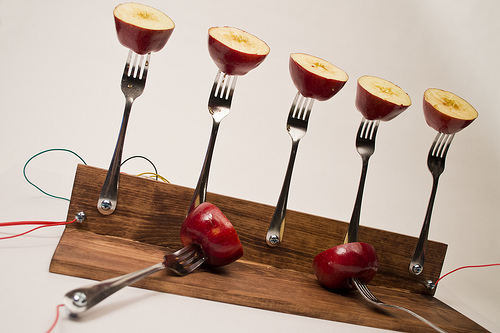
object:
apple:
[313, 241, 379, 293]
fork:
[350, 275, 447, 332]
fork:
[97, 50, 152, 216]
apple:
[113, 2, 177, 55]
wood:
[47, 163, 489, 332]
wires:
[23, 148, 88, 201]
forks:
[409, 131, 457, 277]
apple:
[181, 201, 244, 268]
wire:
[120, 155, 158, 181]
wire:
[0, 217, 78, 239]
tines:
[120, 49, 149, 99]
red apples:
[422, 87, 479, 135]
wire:
[137, 172, 170, 184]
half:
[207, 25, 270, 76]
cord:
[434, 262, 499, 285]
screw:
[100, 199, 112, 213]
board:
[48, 162, 496, 332]